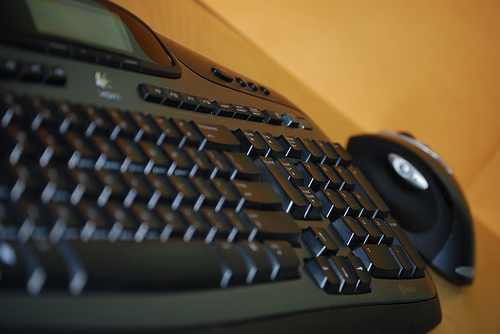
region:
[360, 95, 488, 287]
the mouse is to the right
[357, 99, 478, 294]
the mouse is black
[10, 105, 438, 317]
the keyboard is black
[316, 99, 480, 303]
the mouse is on the desk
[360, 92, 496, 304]
the mouse is a little blurry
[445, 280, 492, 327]
the desk is tan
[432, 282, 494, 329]
the desk is made of wood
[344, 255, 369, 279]
an arrow pointing right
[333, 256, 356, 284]
an arrow pointing down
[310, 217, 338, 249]
an arrow pointing up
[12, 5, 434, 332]
This is a keyboard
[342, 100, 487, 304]
This is a mouse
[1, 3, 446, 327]
The keyboard is black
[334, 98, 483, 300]
The mouse is black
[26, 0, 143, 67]
There is a screen on the keyboard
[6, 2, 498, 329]
The keyboard and mouse are on a desk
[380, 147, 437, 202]
The mouse buttons are silver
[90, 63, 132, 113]
Logo on the keyboard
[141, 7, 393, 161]
This is a wooden desl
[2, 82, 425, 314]
The keys are black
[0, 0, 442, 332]
black plastic computer keyboard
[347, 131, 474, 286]
black optical mouse is out of focus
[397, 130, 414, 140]
scroll wheel of mouse is blurry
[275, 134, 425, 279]
numeric keypad part of keyboard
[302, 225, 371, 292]
right, left, up, down arrow keys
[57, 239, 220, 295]
out of focus black space bar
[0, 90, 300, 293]
alphanumeric portion of the keyboard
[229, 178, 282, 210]
black enter key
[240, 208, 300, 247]
black right side shift key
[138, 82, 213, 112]
four black function keys of the keyboard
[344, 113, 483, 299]
mouse next to keyboard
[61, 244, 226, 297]
space bar on a keyboard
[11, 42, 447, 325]
black keyboard to a computer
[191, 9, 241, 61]
wooden desk where keyboard is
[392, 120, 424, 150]
button on a mouse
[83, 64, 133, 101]
brand of a keyboard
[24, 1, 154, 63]
screen on top of keyboard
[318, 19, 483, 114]
beige wall of a room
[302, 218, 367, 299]
arrow buttons on a keyboard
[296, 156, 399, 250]
number buttons on a keyboard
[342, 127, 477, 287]
Wireless mouse on table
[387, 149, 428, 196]
Control button on mouse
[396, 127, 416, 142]
Scroll wheel on computer mouse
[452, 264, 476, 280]
Company logo on mouse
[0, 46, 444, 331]
Black computer keyboard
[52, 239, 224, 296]
Spacebar key on keyboard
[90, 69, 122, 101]
Keyboard manufacturer identification label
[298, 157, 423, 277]
Number pad on keyboard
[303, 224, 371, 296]
Directional arrow keys on keyboard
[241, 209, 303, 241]
Shift key on keyboard